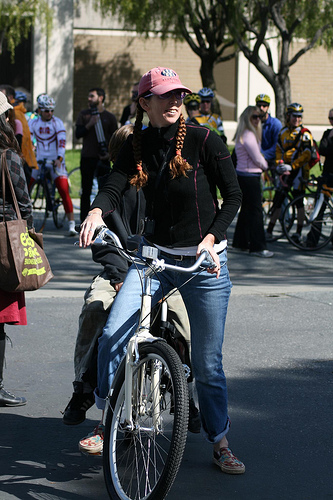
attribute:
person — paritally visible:
[62, 125, 203, 441]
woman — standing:
[231, 105, 275, 257]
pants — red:
[26, 165, 75, 223]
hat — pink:
[133, 66, 195, 100]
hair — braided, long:
[130, 93, 192, 193]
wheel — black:
[102, 336, 191, 500]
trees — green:
[2, 5, 332, 124]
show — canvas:
[76, 430, 114, 455]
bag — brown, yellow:
[3, 160, 55, 292]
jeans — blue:
[95, 242, 234, 443]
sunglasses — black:
[40, 107, 54, 114]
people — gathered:
[0, 83, 332, 260]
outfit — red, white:
[29, 112, 78, 236]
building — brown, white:
[3, 2, 333, 146]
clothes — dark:
[75, 108, 120, 226]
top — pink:
[233, 129, 269, 175]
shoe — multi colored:
[79, 431, 109, 456]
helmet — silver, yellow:
[285, 101, 303, 117]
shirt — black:
[88, 119, 245, 249]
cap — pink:
[136, 65, 196, 99]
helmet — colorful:
[182, 92, 201, 108]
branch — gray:
[235, 29, 277, 85]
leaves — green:
[3, 0, 333, 54]